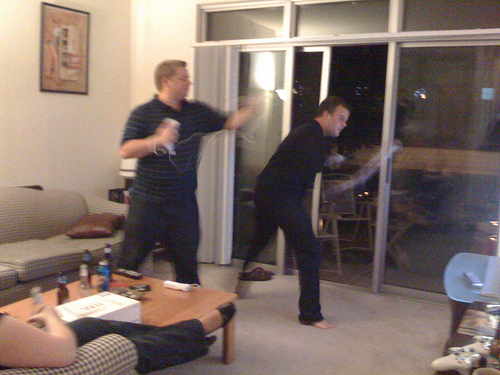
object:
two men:
[117, 60, 353, 329]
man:
[117, 60, 265, 286]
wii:
[153, 118, 182, 157]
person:
[0, 301, 237, 375]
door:
[383, 44, 500, 305]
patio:
[241, 40, 498, 301]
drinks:
[96, 260, 110, 291]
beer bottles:
[103, 244, 114, 281]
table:
[436, 309, 500, 375]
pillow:
[65, 212, 124, 238]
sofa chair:
[0, 333, 139, 375]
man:
[241, 96, 353, 328]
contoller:
[430, 342, 491, 374]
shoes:
[237, 271, 272, 280]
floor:
[149, 262, 452, 373]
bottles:
[78, 249, 92, 289]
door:
[284, 43, 388, 289]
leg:
[127, 319, 199, 375]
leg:
[64, 317, 161, 347]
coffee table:
[0, 272, 239, 364]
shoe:
[215, 301, 236, 328]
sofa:
[0, 185, 153, 307]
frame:
[39, 0, 89, 95]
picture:
[42, 4, 88, 93]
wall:
[1, 0, 131, 206]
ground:
[153, 259, 493, 372]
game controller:
[164, 280, 192, 291]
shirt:
[121, 94, 228, 204]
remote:
[115, 268, 143, 280]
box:
[54, 291, 142, 325]